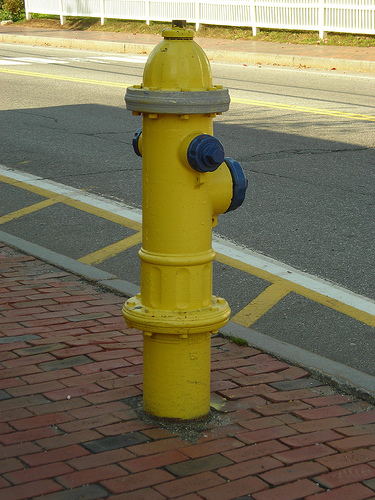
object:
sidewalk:
[2, 227, 375, 497]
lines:
[1, 190, 68, 228]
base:
[136, 389, 220, 435]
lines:
[0, 57, 147, 71]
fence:
[18, 1, 373, 42]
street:
[1, 42, 374, 373]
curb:
[0, 228, 140, 296]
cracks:
[250, 140, 363, 191]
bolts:
[133, 130, 141, 158]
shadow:
[2, 97, 372, 372]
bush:
[2, 1, 27, 19]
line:
[234, 92, 373, 126]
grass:
[73, 18, 374, 49]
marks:
[42, 57, 108, 70]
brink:
[74, 62, 122, 79]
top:
[126, 20, 231, 114]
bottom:
[124, 288, 232, 422]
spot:
[65, 396, 73, 399]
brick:
[73, 443, 134, 468]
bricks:
[10, 394, 80, 426]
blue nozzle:
[189, 132, 224, 172]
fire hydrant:
[123, 27, 248, 422]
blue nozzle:
[224, 158, 248, 209]